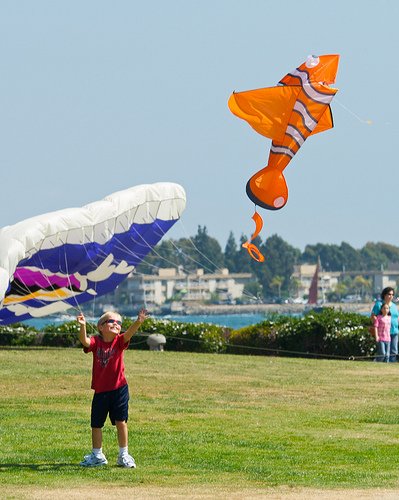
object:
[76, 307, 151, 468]
boy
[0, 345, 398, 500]
grass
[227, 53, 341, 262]
kite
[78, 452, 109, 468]
shoe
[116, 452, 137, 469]
shoe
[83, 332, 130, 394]
shirt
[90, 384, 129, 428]
shorts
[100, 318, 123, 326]
sunglasses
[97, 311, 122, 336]
hair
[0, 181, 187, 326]
kite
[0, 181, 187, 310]
edge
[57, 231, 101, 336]
string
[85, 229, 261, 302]
string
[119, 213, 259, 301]
string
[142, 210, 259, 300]
string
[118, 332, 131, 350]
sleeve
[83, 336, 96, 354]
sleeve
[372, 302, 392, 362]
girl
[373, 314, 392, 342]
shirt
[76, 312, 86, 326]
hand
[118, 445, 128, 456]
sock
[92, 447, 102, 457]
sock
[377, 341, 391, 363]
jeans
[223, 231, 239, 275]
top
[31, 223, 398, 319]
horizon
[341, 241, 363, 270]
top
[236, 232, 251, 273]
top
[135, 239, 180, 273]
top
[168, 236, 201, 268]
top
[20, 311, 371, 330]
water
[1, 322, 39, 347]
bush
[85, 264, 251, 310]
building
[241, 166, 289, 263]
tail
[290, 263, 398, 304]
hotel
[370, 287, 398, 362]
woman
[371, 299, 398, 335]
shirt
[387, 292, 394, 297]
sunglasses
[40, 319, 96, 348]
bush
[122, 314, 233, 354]
bush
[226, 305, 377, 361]
bush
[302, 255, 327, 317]
boat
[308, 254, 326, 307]
sail